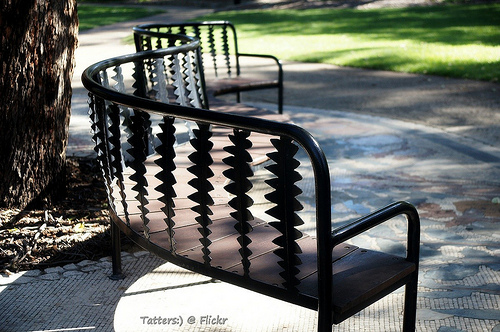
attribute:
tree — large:
[15, 87, 40, 152]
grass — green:
[126, 0, 498, 81]